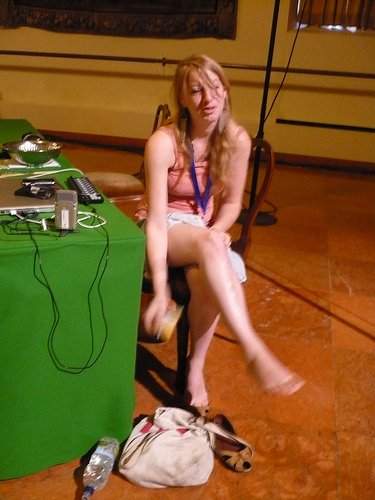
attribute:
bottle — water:
[73, 430, 122, 499]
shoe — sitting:
[208, 409, 259, 478]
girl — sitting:
[141, 52, 315, 420]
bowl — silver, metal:
[6, 134, 66, 168]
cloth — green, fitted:
[2, 116, 141, 491]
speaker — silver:
[53, 190, 81, 234]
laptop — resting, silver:
[0, 173, 77, 215]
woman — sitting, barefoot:
[117, 48, 331, 440]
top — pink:
[149, 119, 237, 219]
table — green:
[1, 118, 145, 480]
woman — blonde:
[135, 52, 306, 407]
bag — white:
[117, 408, 253, 488]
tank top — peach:
[136, 124, 243, 220]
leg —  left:
[178, 269, 220, 406]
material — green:
[0, 117, 146, 477]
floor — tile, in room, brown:
[0, 143, 375, 498]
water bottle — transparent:
[76, 432, 121, 498]